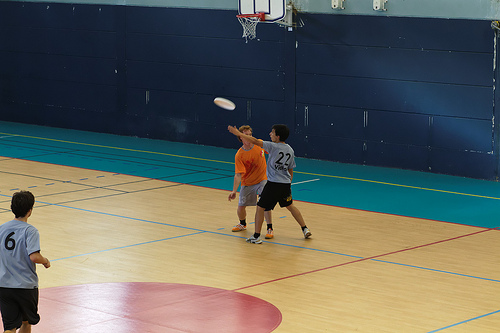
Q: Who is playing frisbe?
A: The boys.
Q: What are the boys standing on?
A: Basketball court.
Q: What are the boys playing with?
A: Frisbee.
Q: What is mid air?
A: Frisbee.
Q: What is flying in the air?
A: Frisbee.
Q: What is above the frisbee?
A: Basketball hoop.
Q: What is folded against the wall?
A: Bleachers.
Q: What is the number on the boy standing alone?
A: 6.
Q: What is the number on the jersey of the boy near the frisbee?
A: 22.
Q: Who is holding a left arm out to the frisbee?
A: Boy wearing 22.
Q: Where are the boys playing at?
A: Gymnasium.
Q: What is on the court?
A: A large red circle.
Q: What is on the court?
A: A yellow line.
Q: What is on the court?
A: A red line.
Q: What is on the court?
A: Blue lines.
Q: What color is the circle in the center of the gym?
A: Red.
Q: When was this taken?
A: During the day.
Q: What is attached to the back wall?
A: A basketball hoop.